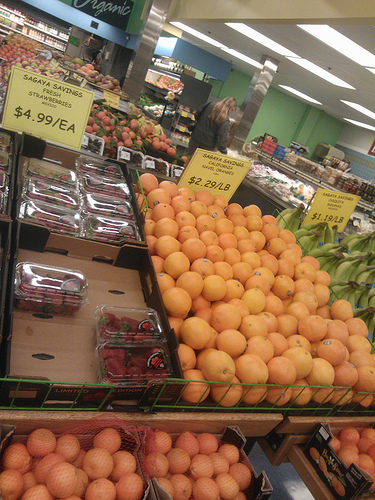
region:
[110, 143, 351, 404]
oranges on display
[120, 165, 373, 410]
oranges on the shelf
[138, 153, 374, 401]
a pile of oranges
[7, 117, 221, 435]
strawberries on a shelf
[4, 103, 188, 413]
strawberries that are for sale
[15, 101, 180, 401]
strawberries in clear containers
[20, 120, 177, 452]
strawberries that are in a store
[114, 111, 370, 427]
oranges in a store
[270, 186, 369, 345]
bananas that are in a store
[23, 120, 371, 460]
fruits that are on display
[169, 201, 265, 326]
a pile of oranges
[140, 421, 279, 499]
oranges inside a rectangle box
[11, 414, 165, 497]
oranges in plastic mesh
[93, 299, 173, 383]
strawberries inside clear plastic containers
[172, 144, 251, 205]
yellow sign with black letters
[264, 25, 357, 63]
bright florescent lighting in the ceiling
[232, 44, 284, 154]
square steel covered beam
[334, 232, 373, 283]
lots of banana bunches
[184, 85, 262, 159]
lady with gray sweater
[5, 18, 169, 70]
fruits inside a supermarket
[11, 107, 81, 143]
A price written as "$4.99/EA"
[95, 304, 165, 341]
A pack of strawberries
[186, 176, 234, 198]
A price written as "$2.99/LB"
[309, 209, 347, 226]
A price written as "$1.19/LB"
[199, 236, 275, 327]
A group of oranges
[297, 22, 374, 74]
A big wall light.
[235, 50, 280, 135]
A big steel pillar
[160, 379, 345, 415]
A green fencing material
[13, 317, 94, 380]
A cardboard plane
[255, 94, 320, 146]
A big green wall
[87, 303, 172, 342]
a conatiner of red strawberries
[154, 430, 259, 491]
a bag of yellow lemons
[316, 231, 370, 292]
a row of yellow bananas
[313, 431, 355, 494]
a box with fruit in it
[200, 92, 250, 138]
a woman shopping in a store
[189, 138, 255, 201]
a sign with the price of the fruit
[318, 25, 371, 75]
lights in the ceiling of the store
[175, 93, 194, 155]
a rack with food on it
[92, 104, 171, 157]
fruit piled on a table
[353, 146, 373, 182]
tile on the wall of the store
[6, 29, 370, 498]
Produce in a grocery store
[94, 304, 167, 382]
Strawberries in a grocery store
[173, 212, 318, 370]
Oranges in a grocery store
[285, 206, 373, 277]
Bananas in a grocery store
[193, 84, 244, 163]
A woman in a grocery store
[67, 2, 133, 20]
A sign that says Organic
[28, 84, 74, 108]
A sign that says Fresh Strawberries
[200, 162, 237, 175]
A sign that says Naval Oranges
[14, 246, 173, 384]
Three packs of strawberries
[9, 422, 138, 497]
A bag of oranges